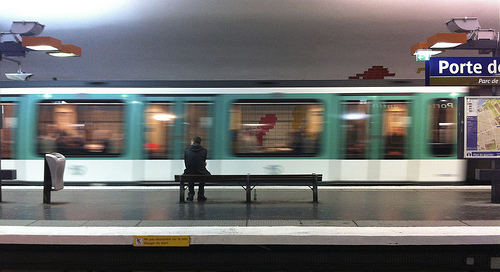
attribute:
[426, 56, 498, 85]
sign — blue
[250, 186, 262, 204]
bottle — green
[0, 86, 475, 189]
train — moving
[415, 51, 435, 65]
sign — green, small